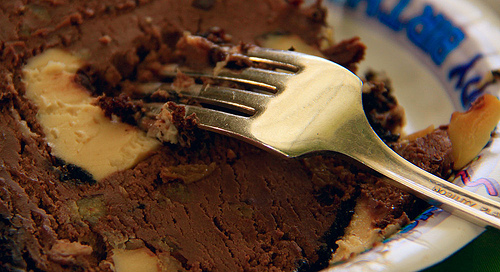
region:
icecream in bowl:
[0, 12, 481, 269]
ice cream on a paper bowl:
[4, 10, 499, 260]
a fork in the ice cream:
[11, 9, 491, 270]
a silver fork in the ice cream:
[7, 6, 486, 267]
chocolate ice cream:
[14, 17, 487, 267]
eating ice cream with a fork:
[18, 0, 499, 230]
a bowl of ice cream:
[9, 7, 494, 270]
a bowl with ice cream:
[10, 12, 472, 262]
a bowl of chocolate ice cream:
[12, 2, 482, 267]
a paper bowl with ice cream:
[15, 5, 493, 257]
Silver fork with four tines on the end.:
[127, 44, 498, 231]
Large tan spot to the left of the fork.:
[16, 50, 160, 176]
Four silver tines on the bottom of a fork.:
[152, 32, 302, 127]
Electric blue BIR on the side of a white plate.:
[406, 3, 468, 67]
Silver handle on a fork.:
[359, 140, 499, 227]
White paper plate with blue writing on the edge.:
[312, 0, 498, 270]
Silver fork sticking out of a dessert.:
[145, 45, 499, 228]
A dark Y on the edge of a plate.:
[446, 52, 483, 89]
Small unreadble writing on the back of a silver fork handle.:
[430, 184, 497, 217]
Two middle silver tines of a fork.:
[150, 62, 278, 106]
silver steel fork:
[151, 23, 497, 207]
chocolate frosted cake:
[1, 1, 251, 267]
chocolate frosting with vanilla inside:
[2, 1, 282, 268]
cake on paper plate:
[0, 2, 495, 246]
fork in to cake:
[6, 6, 403, 215]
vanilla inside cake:
[24, 41, 196, 201]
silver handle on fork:
[361, 58, 451, 270]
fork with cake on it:
[96, 6, 356, 180]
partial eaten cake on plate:
[6, 0, 399, 251]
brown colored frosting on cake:
[108, 157, 338, 264]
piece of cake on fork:
[98, 31, 497, 243]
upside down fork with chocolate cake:
[77, 0, 489, 212]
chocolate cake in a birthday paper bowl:
[3, 5, 495, 270]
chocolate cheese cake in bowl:
[3, 0, 498, 270]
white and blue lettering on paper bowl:
[6, 0, 499, 260]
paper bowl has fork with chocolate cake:
[0, 15, 499, 239]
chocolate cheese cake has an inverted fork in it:
[0, 0, 499, 248]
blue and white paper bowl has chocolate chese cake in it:
[2, 4, 499, 270]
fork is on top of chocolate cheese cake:
[2, 0, 492, 266]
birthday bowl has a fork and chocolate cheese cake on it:
[0, 1, 490, 266]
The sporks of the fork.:
[197, 41, 282, 123]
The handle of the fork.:
[369, 123, 497, 225]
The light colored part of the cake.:
[16, 47, 144, 174]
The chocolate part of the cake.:
[23, 9, 301, 257]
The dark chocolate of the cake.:
[329, 157, 371, 269]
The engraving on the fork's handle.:
[427, 177, 499, 224]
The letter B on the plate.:
[432, 19, 465, 69]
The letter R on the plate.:
[408, 1, 440, 45]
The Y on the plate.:
[440, 52, 477, 89]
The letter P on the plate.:
[457, 80, 497, 109]